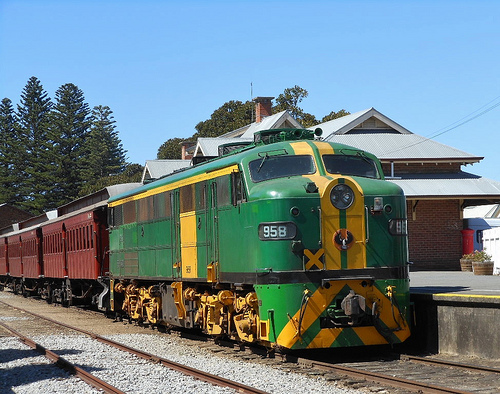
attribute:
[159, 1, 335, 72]
sky — blue, clear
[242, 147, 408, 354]
train — green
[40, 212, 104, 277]
cars — red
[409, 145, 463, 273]
station — building